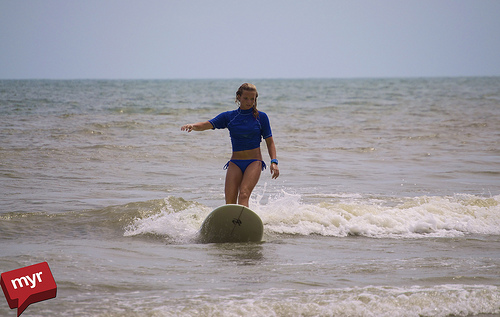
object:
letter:
[8, 271, 48, 288]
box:
[1, 261, 58, 316]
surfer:
[180, 83, 281, 207]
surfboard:
[200, 205, 265, 244]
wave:
[1, 194, 498, 244]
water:
[1, 78, 500, 315]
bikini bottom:
[220, 158, 267, 174]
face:
[240, 90, 256, 108]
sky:
[1, 1, 499, 79]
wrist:
[267, 154, 280, 165]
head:
[236, 83, 259, 110]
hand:
[180, 124, 193, 133]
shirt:
[208, 107, 274, 153]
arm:
[179, 110, 230, 133]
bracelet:
[270, 159, 280, 165]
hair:
[235, 82, 260, 118]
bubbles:
[198, 279, 498, 315]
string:
[230, 206, 245, 235]